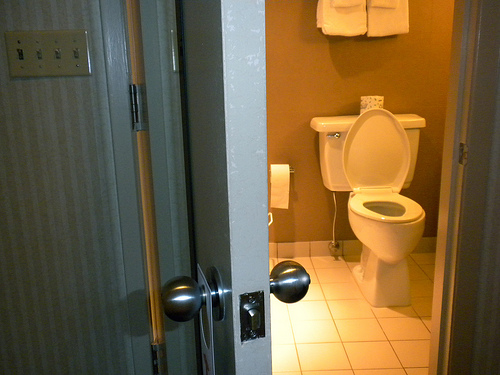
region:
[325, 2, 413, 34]
towel on the wall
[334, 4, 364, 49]
towel on the wall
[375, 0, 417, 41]
towel on the wall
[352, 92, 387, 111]
toilet paper on tank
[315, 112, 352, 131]
tank of the toilet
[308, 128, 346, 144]
lever of the toilet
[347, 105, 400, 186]
lid of the toilet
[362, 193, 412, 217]
seat of the toilet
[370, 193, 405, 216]
bowl of the toilet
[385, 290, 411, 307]
bottom of the toilet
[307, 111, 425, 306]
white toilet in the bathroom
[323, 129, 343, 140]
silver handle on the toilet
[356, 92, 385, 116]
white toilet paper roll on top of the toilet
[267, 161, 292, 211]
white toilet paper hanging from the toilet paper roll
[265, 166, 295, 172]
silver toilet paper holder on the wall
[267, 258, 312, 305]
silver doorknob on the white door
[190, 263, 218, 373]
white paper door hanger on the doorknob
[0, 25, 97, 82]
beige light switches on the wall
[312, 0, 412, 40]
white towels hanging on the wall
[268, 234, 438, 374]
white square tiles on the floor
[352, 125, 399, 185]
a toilet lid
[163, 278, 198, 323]
a doorknob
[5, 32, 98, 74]
a light switch on the wall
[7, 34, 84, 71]
a light switch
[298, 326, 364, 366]
tile on the floor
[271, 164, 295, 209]
toilet tissue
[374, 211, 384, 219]
the toilet sear is white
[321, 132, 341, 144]
a handle on the toilet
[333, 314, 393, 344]
the tile is white on the floor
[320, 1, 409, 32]
the towels hanging are white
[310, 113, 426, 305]
a white toilet in a bathroom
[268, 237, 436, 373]
white tile floor and baseboard in a bathroom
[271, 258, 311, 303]
silver round handle of a door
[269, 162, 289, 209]
a white toilet paper roll on a rack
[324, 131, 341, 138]
a silver flush handle on a toilet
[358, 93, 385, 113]
a wrapped roll of toilet paper on a toilet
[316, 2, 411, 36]
folded white towel hanging against the wall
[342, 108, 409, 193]
a white toilet seat cover that is up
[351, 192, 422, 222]
a white toilet seat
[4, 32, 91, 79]
a set of light switches on the wall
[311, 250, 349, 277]
floor tiles of a restroom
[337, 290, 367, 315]
floor tiles of a restroom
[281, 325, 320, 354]
floor tiles of a restroom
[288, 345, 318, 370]
floor tiles of a restroom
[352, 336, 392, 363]
floor tiles of a restroom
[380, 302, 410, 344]
floor tiles of a restroom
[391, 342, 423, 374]
floor tiles of a restroom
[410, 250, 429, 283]
floor tiles of a restroom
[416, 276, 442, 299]
floor tiles of a restroom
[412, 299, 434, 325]
floor tiles of a restroom